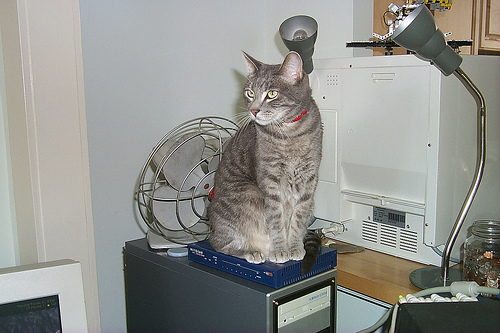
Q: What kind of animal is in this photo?
A: Cat.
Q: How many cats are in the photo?
A: One.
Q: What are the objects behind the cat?
A: Fan and lamp.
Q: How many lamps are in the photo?
A: Two.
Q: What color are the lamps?
A: Silver.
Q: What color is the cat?
A: Grey and black.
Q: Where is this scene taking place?
A: In an office.